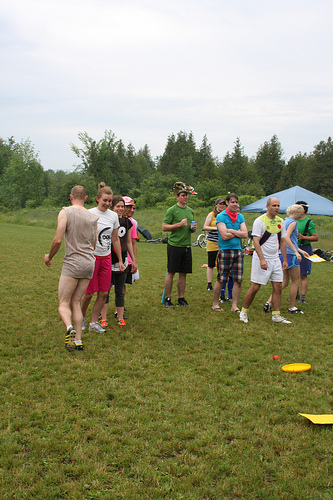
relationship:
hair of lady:
[112, 193, 126, 212] [97, 193, 138, 334]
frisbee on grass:
[280, 360, 315, 378] [1, 216, 331, 500]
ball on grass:
[269, 352, 279, 362] [1, 216, 331, 500]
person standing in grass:
[45, 183, 101, 354] [1, 216, 331, 500]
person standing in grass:
[87, 180, 126, 337] [1, 216, 331, 500]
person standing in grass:
[158, 180, 199, 310] [1, 216, 331, 500]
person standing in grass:
[209, 193, 249, 319] [1, 216, 331, 500]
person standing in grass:
[238, 195, 291, 329] [1, 216, 331, 500]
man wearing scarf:
[209, 193, 249, 319] [223, 209, 241, 230]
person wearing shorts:
[209, 193, 249, 319] [214, 246, 246, 286]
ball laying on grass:
[269, 352, 279, 362] [1, 216, 331, 500]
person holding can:
[158, 180, 199, 310] [189, 217, 198, 233]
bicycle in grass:
[188, 227, 212, 254] [1, 216, 331, 500]